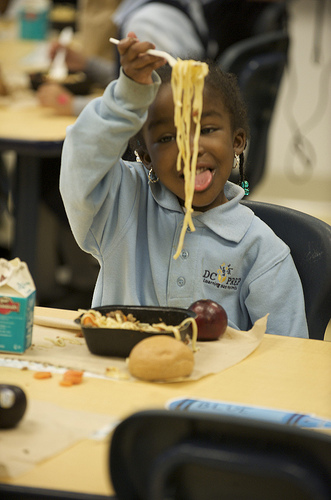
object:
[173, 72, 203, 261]
noodles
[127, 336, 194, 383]
bread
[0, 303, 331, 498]
table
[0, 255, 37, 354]
milk carton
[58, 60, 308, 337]
shirt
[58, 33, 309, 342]
girl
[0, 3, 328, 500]
cafeteria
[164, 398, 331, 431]
crayon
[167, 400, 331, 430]
sign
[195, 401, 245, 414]
word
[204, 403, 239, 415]
blue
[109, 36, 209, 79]
fork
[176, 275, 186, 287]
button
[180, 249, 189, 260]
button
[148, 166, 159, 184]
earring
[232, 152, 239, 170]
earring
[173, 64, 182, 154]
noodles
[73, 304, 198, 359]
container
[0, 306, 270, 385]
paper towel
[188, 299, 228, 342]
apple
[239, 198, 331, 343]
chair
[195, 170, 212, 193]
tongue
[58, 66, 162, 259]
sleeve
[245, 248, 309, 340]
sleeve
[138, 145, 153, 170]
ear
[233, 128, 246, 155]
ear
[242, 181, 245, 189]
beads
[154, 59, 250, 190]
hair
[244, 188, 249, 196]
bead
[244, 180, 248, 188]
bead